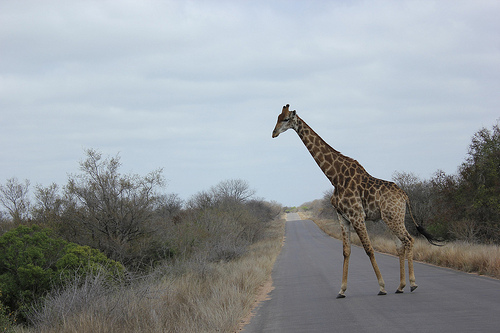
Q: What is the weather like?
A: It is cloudy.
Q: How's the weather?
A: It is cloudy.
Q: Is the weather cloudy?
A: Yes, it is cloudy.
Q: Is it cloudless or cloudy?
A: It is cloudy.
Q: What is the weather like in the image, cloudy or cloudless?
A: It is cloudy.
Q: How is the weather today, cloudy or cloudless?
A: It is cloudy.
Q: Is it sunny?
A: No, it is cloudy.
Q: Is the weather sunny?
A: No, it is cloudy.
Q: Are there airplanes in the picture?
A: No, there are no airplanes.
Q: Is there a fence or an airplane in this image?
A: No, there are no airplanes or fences.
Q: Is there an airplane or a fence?
A: No, there are no airplanes or fences.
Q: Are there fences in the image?
A: No, there are no fences.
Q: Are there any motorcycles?
A: No, there are no motorcycles.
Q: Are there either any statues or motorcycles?
A: No, there are no motorcycles or statues.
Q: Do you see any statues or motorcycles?
A: No, there are no motorcycles or statues.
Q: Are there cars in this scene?
A: No, there are no cars.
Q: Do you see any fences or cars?
A: No, there are no cars or fences.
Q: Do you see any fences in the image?
A: No, there are no fences.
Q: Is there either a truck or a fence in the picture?
A: No, there are no fences or trucks.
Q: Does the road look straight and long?
A: Yes, the road is straight and long.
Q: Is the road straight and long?
A: Yes, the road is straight and long.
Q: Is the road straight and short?
A: No, the road is straight but long.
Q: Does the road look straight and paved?
A: Yes, the road is straight and paved.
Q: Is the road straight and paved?
A: Yes, the road is straight and paved.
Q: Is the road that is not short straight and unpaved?
A: No, the road is straight but paved.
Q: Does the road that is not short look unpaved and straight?
A: No, the road is straight but paved.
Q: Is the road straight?
A: Yes, the road is straight.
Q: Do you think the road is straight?
A: Yes, the road is straight.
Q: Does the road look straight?
A: Yes, the road is straight.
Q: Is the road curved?
A: No, the road is straight.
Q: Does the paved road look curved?
A: No, the road is straight.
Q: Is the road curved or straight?
A: The road is straight.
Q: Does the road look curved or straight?
A: The road is straight.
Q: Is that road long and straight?
A: Yes, the road is long and straight.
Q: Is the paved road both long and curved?
A: No, the road is long but straight.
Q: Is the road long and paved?
A: Yes, the road is long and paved.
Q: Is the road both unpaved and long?
A: No, the road is long but paved.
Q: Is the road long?
A: Yes, the road is long.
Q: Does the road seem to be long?
A: Yes, the road is long.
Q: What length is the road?
A: The road is long.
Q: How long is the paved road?
A: The road is long.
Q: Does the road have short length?
A: No, the road is long.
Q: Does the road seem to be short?
A: No, the road is long.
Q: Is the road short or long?
A: The road is long.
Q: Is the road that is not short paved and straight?
A: Yes, the road is paved and straight.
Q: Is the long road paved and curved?
A: No, the road is paved but straight.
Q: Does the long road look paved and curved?
A: No, the road is paved but straight.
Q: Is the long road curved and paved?
A: No, the road is paved but straight.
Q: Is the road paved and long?
A: Yes, the road is paved and long.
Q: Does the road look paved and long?
A: Yes, the road is paved and long.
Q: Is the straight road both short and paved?
A: No, the road is paved but long.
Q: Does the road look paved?
A: Yes, the road is paved.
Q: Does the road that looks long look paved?
A: Yes, the road is paved.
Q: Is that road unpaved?
A: No, the road is paved.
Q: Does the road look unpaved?
A: No, the road is paved.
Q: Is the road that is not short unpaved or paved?
A: The road is paved.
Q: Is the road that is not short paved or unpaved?
A: The road is paved.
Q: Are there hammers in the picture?
A: No, there are no hammers.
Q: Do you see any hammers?
A: No, there are no hammers.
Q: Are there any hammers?
A: No, there are no hammers.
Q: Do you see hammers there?
A: No, there are no hammers.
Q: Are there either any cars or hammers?
A: No, there are no hammers or cars.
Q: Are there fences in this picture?
A: No, there are no fences.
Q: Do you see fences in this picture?
A: No, there are no fences.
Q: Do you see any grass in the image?
A: Yes, there is grass.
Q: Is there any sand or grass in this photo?
A: Yes, there is grass.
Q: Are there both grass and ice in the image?
A: No, there is grass but no ice.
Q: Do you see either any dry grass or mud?
A: Yes, there is dry grass.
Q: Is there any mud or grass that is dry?
A: Yes, the grass is dry.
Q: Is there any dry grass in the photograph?
A: Yes, there is dry grass.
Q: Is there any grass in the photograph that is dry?
A: Yes, there is grass that is dry.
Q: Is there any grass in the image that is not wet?
A: Yes, there is dry grass.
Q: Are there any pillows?
A: No, there are no pillows.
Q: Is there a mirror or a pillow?
A: No, there are no pillows or mirrors.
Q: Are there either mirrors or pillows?
A: No, there are no pillows or mirrors.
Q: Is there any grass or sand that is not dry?
A: No, there is grass but it is dry.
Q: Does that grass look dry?
A: Yes, the grass is dry.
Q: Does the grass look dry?
A: Yes, the grass is dry.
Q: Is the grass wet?
A: No, the grass is dry.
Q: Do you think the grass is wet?
A: No, the grass is dry.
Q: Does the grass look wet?
A: No, the grass is dry.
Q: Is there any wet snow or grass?
A: No, there is grass but it is dry.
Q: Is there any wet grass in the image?
A: No, there is grass but it is dry.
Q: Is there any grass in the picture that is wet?
A: No, there is grass but it is dry.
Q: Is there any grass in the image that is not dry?
A: No, there is grass but it is dry.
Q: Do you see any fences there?
A: No, there are no fences.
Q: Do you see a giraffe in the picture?
A: Yes, there is a giraffe.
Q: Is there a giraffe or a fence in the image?
A: Yes, there is a giraffe.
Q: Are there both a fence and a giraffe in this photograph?
A: No, there is a giraffe but no fences.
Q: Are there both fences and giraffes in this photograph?
A: No, there is a giraffe but no fences.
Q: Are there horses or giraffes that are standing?
A: Yes, the giraffe is standing.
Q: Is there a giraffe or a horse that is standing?
A: Yes, the giraffe is standing.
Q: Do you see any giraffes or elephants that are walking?
A: Yes, the giraffe is walking.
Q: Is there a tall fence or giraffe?
A: Yes, there is a tall giraffe.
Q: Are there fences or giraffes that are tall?
A: Yes, the giraffe is tall.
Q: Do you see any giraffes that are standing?
A: Yes, there is a giraffe that is standing.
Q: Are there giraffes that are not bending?
A: Yes, there is a giraffe that is standing.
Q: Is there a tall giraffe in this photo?
A: Yes, there is a tall giraffe.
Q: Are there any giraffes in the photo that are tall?
A: Yes, there is a giraffe that is tall.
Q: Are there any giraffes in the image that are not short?
A: Yes, there is a tall giraffe.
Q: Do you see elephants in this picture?
A: No, there are no elephants.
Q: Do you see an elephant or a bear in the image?
A: No, there are no elephants or bears.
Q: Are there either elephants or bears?
A: No, there are no elephants or bears.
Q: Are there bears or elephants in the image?
A: No, there are no elephants or bears.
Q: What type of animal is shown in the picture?
A: The animal is a giraffe.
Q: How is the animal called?
A: The animal is a giraffe.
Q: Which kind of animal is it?
A: The animal is a giraffe.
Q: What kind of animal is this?
A: That is a giraffe.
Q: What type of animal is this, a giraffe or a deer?
A: That is a giraffe.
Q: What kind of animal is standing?
A: The animal is a giraffe.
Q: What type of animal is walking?
A: The animal is a giraffe.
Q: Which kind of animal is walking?
A: The animal is a giraffe.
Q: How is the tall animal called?
A: The animal is a giraffe.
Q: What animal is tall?
A: The animal is a giraffe.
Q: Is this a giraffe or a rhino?
A: This is a giraffe.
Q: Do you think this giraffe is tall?
A: Yes, the giraffe is tall.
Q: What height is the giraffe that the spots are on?
A: The giraffe is tall.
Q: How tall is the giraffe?
A: The giraffe is tall.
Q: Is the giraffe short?
A: No, the giraffe is tall.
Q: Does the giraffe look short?
A: No, the giraffe is tall.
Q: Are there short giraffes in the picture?
A: No, there is a giraffe but it is tall.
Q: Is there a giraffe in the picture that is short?
A: No, there is a giraffe but it is tall.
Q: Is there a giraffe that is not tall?
A: No, there is a giraffe but it is tall.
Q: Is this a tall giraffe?
A: Yes, this is a tall giraffe.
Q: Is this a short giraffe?
A: No, this is a tall giraffe.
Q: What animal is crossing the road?
A: The animal is a giraffe.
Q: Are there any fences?
A: No, there are no fences.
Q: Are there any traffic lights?
A: No, there are no traffic lights.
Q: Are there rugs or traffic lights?
A: No, there are no traffic lights or rugs.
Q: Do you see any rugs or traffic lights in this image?
A: No, there are no traffic lights or rugs.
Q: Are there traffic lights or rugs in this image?
A: No, there are no traffic lights or rugs.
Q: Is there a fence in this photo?
A: No, there are no fences.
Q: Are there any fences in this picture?
A: No, there are no fences.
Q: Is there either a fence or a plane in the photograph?
A: No, there are no fences or airplanes.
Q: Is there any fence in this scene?
A: No, there are no fences.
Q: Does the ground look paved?
A: Yes, the ground is paved.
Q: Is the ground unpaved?
A: No, the ground is paved.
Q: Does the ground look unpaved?
A: No, the ground is paved.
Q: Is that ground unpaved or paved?
A: The ground is paved.